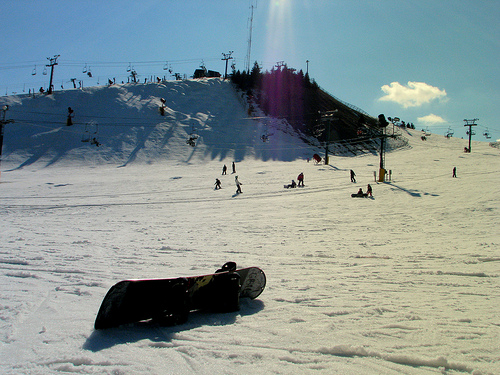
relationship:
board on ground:
[92, 259, 267, 330] [303, 286, 410, 321]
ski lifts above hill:
[21, 49, 238, 70] [188, 82, 264, 115]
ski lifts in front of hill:
[311, 106, 484, 162] [188, 82, 264, 115]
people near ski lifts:
[195, 154, 384, 203] [21, 49, 238, 70]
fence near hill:
[341, 97, 366, 117] [270, 69, 321, 113]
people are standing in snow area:
[195, 154, 384, 203] [260, 194, 311, 226]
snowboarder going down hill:
[182, 133, 205, 148] [200, 103, 225, 133]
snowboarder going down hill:
[254, 127, 274, 144] [200, 103, 225, 133]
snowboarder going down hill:
[157, 96, 169, 119] [200, 103, 225, 133]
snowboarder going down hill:
[60, 103, 78, 129] [200, 103, 225, 133]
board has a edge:
[179, 266, 272, 309] [249, 262, 269, 282]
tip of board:
[95, 311, 105, 327] [179, 266, 272, 309]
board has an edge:
[179, 266, 272, 309] [249, 262, 269, 282]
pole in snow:
[378, 136, 388, 167] [178, 121, 216, 133]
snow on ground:
[178, 121, 216, 133] [303, 286, 410, 321]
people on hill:
[195, 154, 384, 203] [188, 82, 264, 115]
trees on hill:
[241, 58, 309, 82] [188, 82, 264, 115]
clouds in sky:
[368, 61, 458, 127] [284, 9, 388, 44]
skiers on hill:
[283, 170, 381, 200] [188, 82, 264, 115]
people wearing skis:
[195, 154, 384, 203] [209, 183, 242, 197]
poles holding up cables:
[369, 112, 479, 157] [334, 112, 375, 134]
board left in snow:
[92, 259, 267, 330] [178, 121, 216, 133]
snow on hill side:
[178, 121, 216, 133] [0, 72, 380, 171]